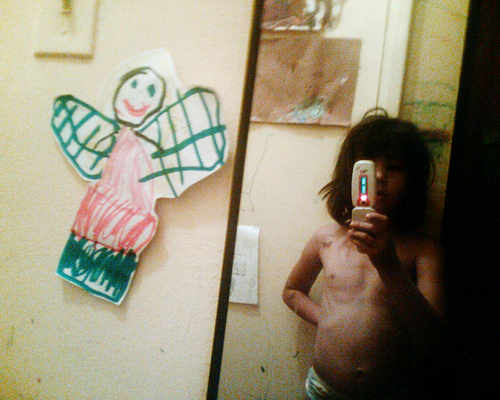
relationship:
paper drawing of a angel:
[40, 47, 233, 310] [47, 64, 227, 190]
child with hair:
[282, 115, 447, 399] [365, 117, 413, 151]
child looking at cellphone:
[282, 115, 447, 399] [353, 163, 371, 217]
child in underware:
[282, 115, 447, 399] [308, 372, 327, 400]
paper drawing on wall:
[40, 47, 233, 310] [132, 17, 204, 53]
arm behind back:
[292, 292, 322, 327] [318, 275, 325, 299]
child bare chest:
[282, 115, 447, 399] [337, 247, 370, 273]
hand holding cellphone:
[349, 210, 391, 254] [353, 163, 371, 217]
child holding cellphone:
[282, 115, 447, 399] [353, 163, 371, 217]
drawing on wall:
[93, 64, 183, 139] [132, 17, 204, 53]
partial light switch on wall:
[37, 2, 101, 21] [132, 17, 204, 53]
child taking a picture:
[282, 115, 447, 399] [373, 156, 404, 185]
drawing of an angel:
[93, 64, 183, 139] [47, 64, 227, 190]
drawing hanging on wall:
[93, 64, 183, 139] [132, 17, 204, 53]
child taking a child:
[282, 115, 447, 399] [282, 115, 447, 399]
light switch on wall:
[34, 3, 99, 58] [132, 17, 204, 53]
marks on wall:
[435, 121, 453, 152] [132, 17, 204, 53]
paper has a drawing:
[281, 72, 352, 127] [93, 64, 183, 139]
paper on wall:
[281, 72, 352, 127] [132, 17, 204, 53]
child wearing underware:
[282, 115, 447, 399] [308, 372, 327, 400]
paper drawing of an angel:
[40, 47, 233, 310] [47, 64, 227, 190]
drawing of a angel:
[93, 64, 183, 139] [47, 64, 227, 190]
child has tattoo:
[282, 115, 447, 399] [321, 237, 335, 251]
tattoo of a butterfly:
[321, 237, 335, 251] [322, 241, 331, 248]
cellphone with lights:
[353, 163, 371, 217] [360, 187, 369, 199]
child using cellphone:
[282, 116, 454, 398] [353, 163, 371, 217]